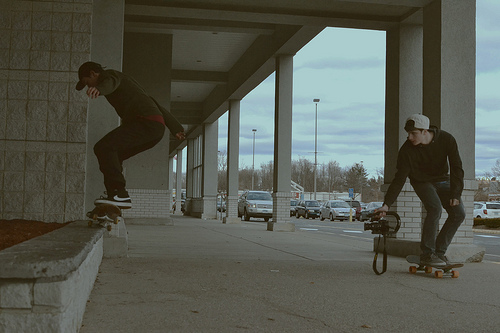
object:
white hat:
[403, 113, 430, 131]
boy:
[373, 113, 466, 265]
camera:
[363, 218, 395, 234]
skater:
[75, 61, 186, 209]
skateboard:
[405, 255, 464, 278]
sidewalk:
[78, 214, 500, 333]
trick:
[85, 189, 132, 231]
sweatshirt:
[379, 124, 464, 208]